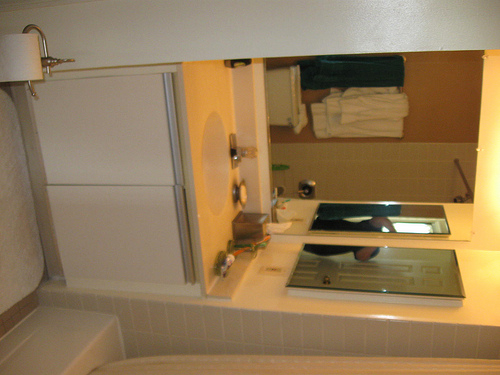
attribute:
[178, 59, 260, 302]
sink — white, huge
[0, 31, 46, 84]
toilet paper — white, roll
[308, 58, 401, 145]
towels — white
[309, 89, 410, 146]
towels — white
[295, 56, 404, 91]
towel — blue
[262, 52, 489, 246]
mirror — small, large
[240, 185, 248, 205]
soap — white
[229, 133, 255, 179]
faucet — silver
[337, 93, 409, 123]
towel — white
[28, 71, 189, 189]
door — white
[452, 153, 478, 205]
shower curtain rod — metal